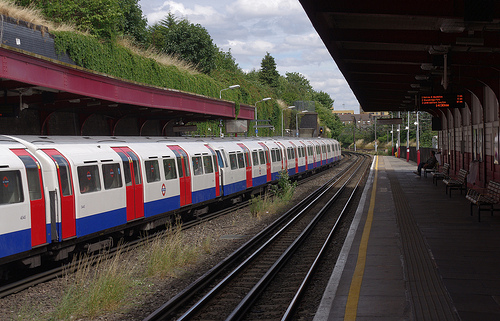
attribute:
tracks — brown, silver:
[141, 149, 371, 320]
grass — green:
[43, 245, 145, 320]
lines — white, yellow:
[313, 155, 381, 320]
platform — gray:
[311, 153, 499, 320]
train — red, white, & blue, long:
[0, 133, 345, 272]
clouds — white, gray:
[145, 0, 358, 115]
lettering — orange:
[421, 94, 448, 108]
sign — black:
[414, 91, 466, 110]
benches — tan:
[419, 156, 498, 221]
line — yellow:
[344, 140, 379, 320]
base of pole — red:
[414, 149, 421, 166]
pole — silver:
[413, 111, 421, 151]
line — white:
[312, 155, 375, 319]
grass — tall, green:
[250, 176, 295, 221]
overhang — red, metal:
[0, 45, 257, 136]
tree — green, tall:
[256, 51, 281, 89]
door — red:
[110, 144, 146, 221]